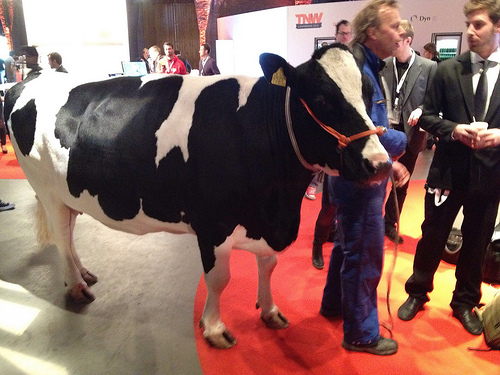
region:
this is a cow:
[8, 35, 384, 321]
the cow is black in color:
[209, 133, 284, 206]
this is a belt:
[330, 128, 358, 150]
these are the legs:
[187, 249, 289, 359]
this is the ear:
[260, 50, 296, 88]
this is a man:
[428, 0, 496, 319]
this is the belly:
[54, 110, 165, 221]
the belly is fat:
[55, 111, 151, 221]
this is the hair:
[356, 9, 382, 25]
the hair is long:
[356, 9, 374, 29]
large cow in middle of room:
[2, 44, 403, 349]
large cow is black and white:
[1, 38, 401, 358]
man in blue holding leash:
[321, 1, 426, 366]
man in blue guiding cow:
[316, 1, 418, 358]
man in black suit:
[398, 0, 499, 340]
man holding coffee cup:
[461, 114, 488, 156]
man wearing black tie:
[473, 58, 491, 129]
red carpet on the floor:
[173, 167, 498, 374]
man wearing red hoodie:
[150, 38, 188, 79]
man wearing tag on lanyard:
[383, 50, 423, 133]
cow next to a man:
[6, 45, 398, 347]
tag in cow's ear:
[258, 59, 293, 88]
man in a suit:
[401, 4, 493, 357]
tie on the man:
[472, 55, 492, 130]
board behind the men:
[213, 5, 499, 133]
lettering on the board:
[292, 2, 333, 30]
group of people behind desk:
[135, 41, 239, 78]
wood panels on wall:
[126, 3, 291, 64]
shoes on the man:
[313, 306, 397, 354]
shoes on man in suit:
[398, 297, 487, 335]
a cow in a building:
[43, 22, 483, 364]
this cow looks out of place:
[31, 14, 477, 302]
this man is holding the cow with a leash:
[30, 7, 445, 302]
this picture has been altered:
[10, 17, 495, 367]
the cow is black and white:
[1, 48, 348, 357]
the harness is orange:
[295, 89, 385, 159]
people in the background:
[117, 39, 234, 68]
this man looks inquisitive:
[436, 4, 499, 251]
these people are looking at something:
[10, 38, 67, 77]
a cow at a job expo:
[12, 12, 464, 301]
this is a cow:
[64, 68, 344, 328]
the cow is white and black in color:
[152, 101, 216, 168]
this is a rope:
[364, 104, 401, 149]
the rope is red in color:
[350, 125, 371, 137]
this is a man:
[430, 0, 499, 305]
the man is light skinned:
[477, 17, 488, 41]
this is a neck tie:
[475, 63, 490, 120]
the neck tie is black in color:
[475, 70, 487, 101]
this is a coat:
[438, 68, 460, 106]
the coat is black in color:
[434, 67, 461, 107]